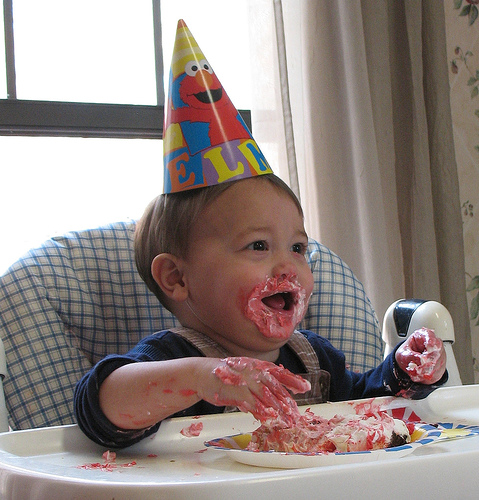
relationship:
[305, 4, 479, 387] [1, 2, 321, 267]
curtain by window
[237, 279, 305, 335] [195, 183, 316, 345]
cream on face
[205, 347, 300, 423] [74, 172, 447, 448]
hand of child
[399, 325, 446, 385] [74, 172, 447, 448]
hand of child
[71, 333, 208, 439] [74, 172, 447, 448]
sleeve of child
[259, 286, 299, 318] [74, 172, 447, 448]
mouth on child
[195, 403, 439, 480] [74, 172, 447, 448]
plate before child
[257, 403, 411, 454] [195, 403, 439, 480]
cake on plate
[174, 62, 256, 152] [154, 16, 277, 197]
elmo on party hat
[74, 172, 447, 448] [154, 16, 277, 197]
child wearing party hat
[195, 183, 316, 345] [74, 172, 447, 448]
face of child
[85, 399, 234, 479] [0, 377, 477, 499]
frosting on th table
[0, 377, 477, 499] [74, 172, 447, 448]
table before child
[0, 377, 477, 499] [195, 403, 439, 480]
table with plate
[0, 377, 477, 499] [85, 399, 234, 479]
table with frosting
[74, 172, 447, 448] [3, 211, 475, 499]
child sitting in high chair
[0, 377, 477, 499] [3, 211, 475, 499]
table on high chair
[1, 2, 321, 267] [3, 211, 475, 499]
window behind high chair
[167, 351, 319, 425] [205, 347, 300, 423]
frosting on hand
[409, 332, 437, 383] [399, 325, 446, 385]
frosting on hand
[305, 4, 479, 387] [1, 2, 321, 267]
curtain next to window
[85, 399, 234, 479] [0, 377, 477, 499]
frosting on table